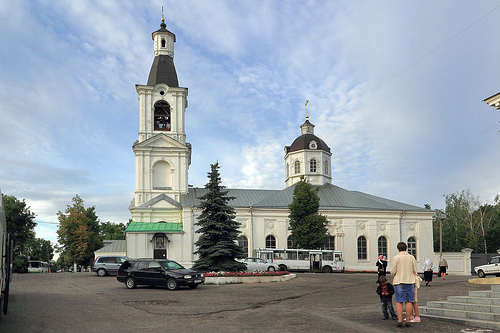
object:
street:
[12, 272, 99, 332]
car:
[116, 258, 208, 290]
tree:
[190, 160, 247, 271]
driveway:
[296, 266, 489, 332]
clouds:
[274, 57, 353, 99]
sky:
[0, 5, 125, 194]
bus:
[253, 248, 345, 273]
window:
[150, 97, 173, 133]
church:
[92, 52, 475, 273]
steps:
[410, 284, 500, 328]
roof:
[186, 185, 434, 208]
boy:
[374, 275, 397, 319]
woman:
[387, 242, 417, 327]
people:
[422, 257, 435, 286]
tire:
[165, 278, 180, 291]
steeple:
[283, 98, 332, 153]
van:
[92, 255, 137, 277]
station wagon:
[116, 258, 205, 289]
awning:
[126, 219, 184, 232]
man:
[376, 255, 388, 281]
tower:
[145, 6, 183, 88]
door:
[310, 252, 322, 272]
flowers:
[233, 272, 236, 275]